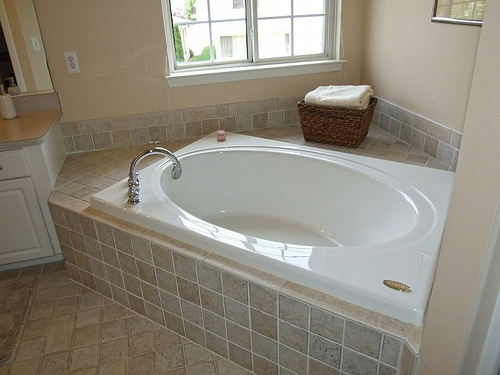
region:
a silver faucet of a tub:
[126, 147, 182, 197]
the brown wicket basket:
[296, 98, 376, 145]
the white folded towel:
[305, 81, 367, 103]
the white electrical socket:
[62, 50, 79, 74]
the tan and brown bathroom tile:
[151, 242, 171, 269]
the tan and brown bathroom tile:
[168, 250, 196, 279]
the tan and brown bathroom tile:
[192, 259, 223, 291]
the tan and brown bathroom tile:
[217, 268, 249, 303]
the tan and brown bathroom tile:
[244, 280, 279, 314]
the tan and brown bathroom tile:
[278, 295, 308, 327]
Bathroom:
[1, 3, 498, 371]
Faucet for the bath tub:
[125, 141, 182, 208]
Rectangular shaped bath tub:
[90, 126, 454, 327]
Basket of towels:
[297, 81, 381, 149]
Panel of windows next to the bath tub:
[157, 1, 347, 84]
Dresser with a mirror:
[1, 2, 71, 276]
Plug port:
[61, 43, 82, 81]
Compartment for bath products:
[432, 1, 484, 26]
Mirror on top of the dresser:
[1, 1, 63, 119]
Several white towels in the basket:
[302, 81, 373, 111]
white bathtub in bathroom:
[87, 125, 460, 336]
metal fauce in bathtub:
[114, 135, 189, 207]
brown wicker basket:
[287, 93, 385, 150]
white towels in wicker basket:
[295, 78, 384, 152]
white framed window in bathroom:
[158, 2, 350, 88]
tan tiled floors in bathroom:
[2, 267, 243, 372]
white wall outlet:
[58, 44, 92, 84]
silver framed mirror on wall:
[425, 0, 487, 39]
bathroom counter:
[0, 112, 66, 284]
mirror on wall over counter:
[1, 0, 59, 105]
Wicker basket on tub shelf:
[293, 98, 382, 151]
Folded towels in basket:
[298, 83, 379, 155]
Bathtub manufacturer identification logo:
[378, 273, 414, 299]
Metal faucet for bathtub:
[122, 142, 184, 204]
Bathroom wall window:
[163, 3, 342, 73]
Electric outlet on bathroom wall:
[62, 48, 83, 75]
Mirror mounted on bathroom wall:
[1, 0, 59, 97]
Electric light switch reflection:
[29, 34, 42, 54]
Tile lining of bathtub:
[50, 116, 459, 371]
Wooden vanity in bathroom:
[4, 95, 67, 275]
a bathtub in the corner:
[98, 123, 457, 324]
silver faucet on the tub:
[122, 148, 184, 205]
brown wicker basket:
[297, 100, 376, 146]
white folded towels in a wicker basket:
[305, 83, 368, 109]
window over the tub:
[165, 2, 348, 79]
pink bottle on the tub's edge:
[213, 130, 225, 143]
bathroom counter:
[1, 114, 56, 144]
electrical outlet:
[65, 53, 79, 74]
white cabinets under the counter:
[2, 123, 60, 279]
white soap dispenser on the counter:
[1, 83, 15, 120]